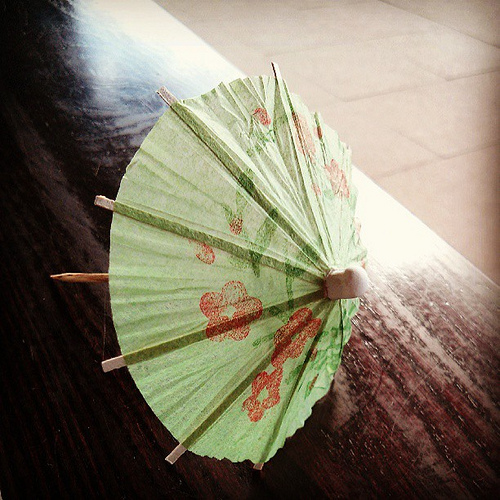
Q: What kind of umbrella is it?
A: Cocktail.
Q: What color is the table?
A: Brown.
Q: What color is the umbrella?
A: Green.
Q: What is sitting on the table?
A: An umbrella.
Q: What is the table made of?
A: Wood.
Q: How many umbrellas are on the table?
A: One.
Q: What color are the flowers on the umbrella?
A: Red.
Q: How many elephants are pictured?
A: Zero.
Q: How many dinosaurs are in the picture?
A: Zero.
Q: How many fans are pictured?
A: One.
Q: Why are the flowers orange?
A: Design.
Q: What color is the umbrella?
A: Green.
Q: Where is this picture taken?
A: Table.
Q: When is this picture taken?
A: At a window.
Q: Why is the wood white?
A: Sunshine.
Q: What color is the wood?
A: Brown.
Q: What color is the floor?
A: White.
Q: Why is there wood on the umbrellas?
A: Support.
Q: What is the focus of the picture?
A: Toothpick umbrella.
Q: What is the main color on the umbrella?
A: Green.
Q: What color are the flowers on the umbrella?
A: Red.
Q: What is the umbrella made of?
A: Toothpicks and paper.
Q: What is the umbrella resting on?
A: Wood.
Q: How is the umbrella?
A: Open.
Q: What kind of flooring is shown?
A: Tiles.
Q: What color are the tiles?
A: Beige.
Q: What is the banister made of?
A: Wood.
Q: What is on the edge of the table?
A: Light.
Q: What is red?
A: Flowers.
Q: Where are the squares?
A: Top right.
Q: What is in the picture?
A: Umbrella.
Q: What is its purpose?
A: Drink decoration.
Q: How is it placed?
A: Sideways.